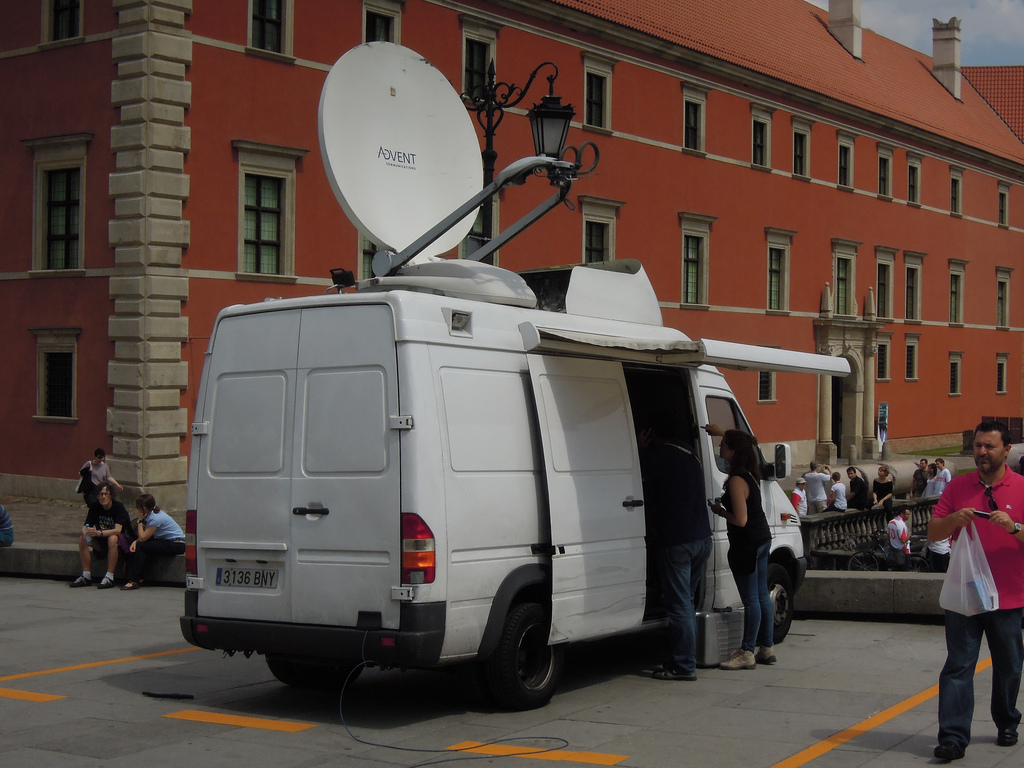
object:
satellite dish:
[318, 41, 483, 256]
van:
[184, 259, 850, 712]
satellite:
[318, 31, 512, 267]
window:
[586, 72, 602, 128]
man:
[928, 421, 1023, 758]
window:
[753, 119, 762, 165]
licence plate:
[216, 568, 279, 589]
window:
[684, 235, 700, 304]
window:
[685, 100, 698, 151]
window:
[246, 173, 282, 273]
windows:
[769, 248, 778, 309]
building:
[0, 0, 1024, 585]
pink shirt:
[933, 468, 1024, 610]